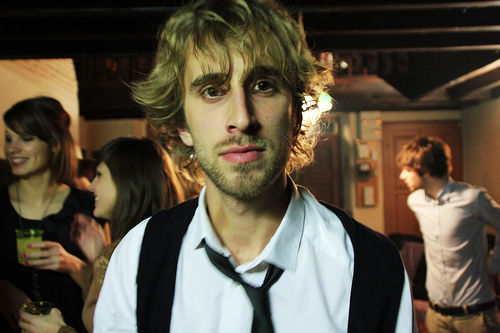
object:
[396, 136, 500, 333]
boy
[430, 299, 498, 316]
belt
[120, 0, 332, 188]
hair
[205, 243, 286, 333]
black tie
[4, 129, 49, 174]
smiling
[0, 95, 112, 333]
girl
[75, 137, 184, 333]
girl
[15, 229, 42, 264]
drink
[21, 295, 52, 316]
drink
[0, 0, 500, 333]
group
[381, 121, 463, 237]
wood door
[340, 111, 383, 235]
back wall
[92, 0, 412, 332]
man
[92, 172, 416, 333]
shirt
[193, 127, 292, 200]
beard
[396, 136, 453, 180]
hair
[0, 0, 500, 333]
room